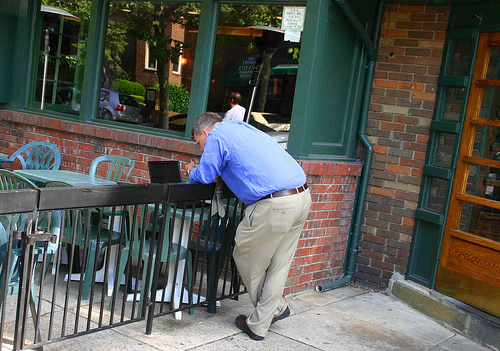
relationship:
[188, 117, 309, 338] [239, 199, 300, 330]
man wearing slacks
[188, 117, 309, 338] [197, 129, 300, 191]
man wearing blue shirt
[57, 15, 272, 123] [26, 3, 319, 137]
reflection in glass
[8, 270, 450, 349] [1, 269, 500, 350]
cement on ground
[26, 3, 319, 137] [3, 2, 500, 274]
window on building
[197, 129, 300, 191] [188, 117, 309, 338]
shirt on man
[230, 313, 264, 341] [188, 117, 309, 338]
shoes on man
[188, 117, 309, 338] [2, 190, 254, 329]
man leaning on fence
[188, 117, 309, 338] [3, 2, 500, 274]
man in front of building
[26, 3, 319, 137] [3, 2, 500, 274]
window in front of building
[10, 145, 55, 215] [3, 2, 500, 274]
chairs in front of building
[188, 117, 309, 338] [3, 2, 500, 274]
man standing in front of building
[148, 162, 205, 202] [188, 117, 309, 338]
computer in front of man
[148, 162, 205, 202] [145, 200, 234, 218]
lap top on table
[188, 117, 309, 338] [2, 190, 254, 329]
man leaning over fence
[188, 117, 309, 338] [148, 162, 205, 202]
man looking at a laptop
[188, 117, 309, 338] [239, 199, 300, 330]
man wearing khaki pants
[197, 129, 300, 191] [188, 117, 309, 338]
blue shirt on man